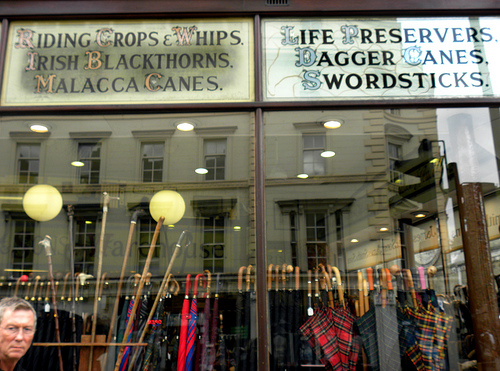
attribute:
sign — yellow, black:
[21, 210, 244, 263]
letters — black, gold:
[14, 26, 92, 57]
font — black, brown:
[8, 22, 248, 102]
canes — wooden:
[73, 170, 193, 320]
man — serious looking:
[4, 300, 40, 369]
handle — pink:
[417, 264, 431, 299]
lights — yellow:
[137, 164, 209, 250]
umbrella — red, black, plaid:
[311, 273, 457, 334]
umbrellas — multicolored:
[3, 262, 455, 369]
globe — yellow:
[141, 183, 186, 228]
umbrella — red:
[165, 259, 207, 362]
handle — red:
[186, 265, 205, 288]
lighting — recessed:
[89, 116, 366, 176]